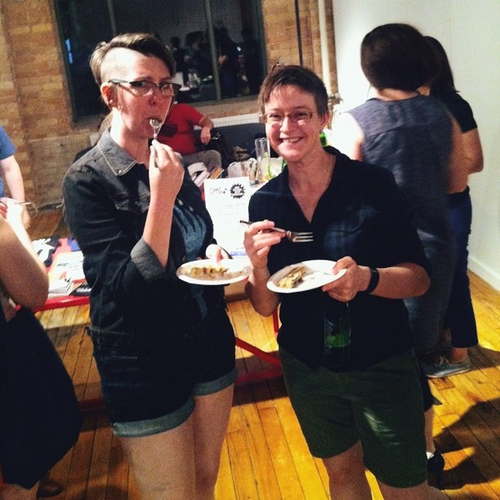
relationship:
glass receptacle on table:
[253, 135, 272, 194] [229, 175, 244, 238]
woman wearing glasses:
[63, 33, 236, 499] [111, 84, 176, 97]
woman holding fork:
[232, 64, 435, 497] [237, 217, 315, 243]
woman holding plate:
[63, 33, 236, 499] [178, 256, 253, 284]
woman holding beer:
[232, 64, 435, 497] [321, 289, 355, 352]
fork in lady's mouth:
[144, 117, 164, 146] [145, 113, 166, 126]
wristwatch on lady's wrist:
[359, 267, 380, 297] [362, 265, 376, 295]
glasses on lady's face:
[106, 73, 176, 98] [126, 55, 174, 134]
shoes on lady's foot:
[429, 358, 478, 379] [419, 33, 486, 373]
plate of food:
[178, 256, 253, 284] [176, 265, 241, 277]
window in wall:
[42, 1, 267, 132] [0, 2, 339, 206]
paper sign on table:
[201, 175, 248, 250] [22, 237, 287, 366]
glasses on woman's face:
[260, 105, 326, 125] [259, 83, 322, 154]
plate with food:
[262, 257, 350, 292] [273, 264, 307, 288]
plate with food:
[178, 256, 253, 284] [185, 263, 239, 280]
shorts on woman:
[87, 323, 239, 439] [63, 33, 236, 499]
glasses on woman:
[111, 84, 176, 97] [63, 33, 236, 499]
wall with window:
[0, 2, 339, 206] [42, 1, 267, 132]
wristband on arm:
[358, 257, 386, 298] [333, 254, 419, 312]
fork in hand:
[237, 219, 314, 242] [241, 213, 289, 270]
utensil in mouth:
[148, 109, 166, 149] [144, 111, 164, 126]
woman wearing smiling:
[232, 64, 435, 497] [273, 133, 306, 142]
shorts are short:
[87, 318, 241, 442] [87, 320, 237, 440]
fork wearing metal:
[231, 219, 311, 251] [237, 216, 316, 244]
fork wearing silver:
[231, 219, 311, 251] [238, 218, 312, 245]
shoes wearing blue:
[429, 358, 478, 379] [431, 355, 454, 375]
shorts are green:
[272, 345, 437, 497] [292, 390, 339, 440]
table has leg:
[16, 219, 295, 386] [224, 323, 286, 369]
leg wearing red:
[224, 323, 286, 369] [238, 337, 252, 347]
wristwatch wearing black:
[359, 265, 381, 297] [367, 278, 376, 288]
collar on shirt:
[94, 126, 135, 178] [62, 127, 246, 367]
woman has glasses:
[63, 33, 236, 499] [102, 68, 180, 101]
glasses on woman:
[260, 105, 326, 125] [232, 64, 435, 497]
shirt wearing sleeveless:
[337, 95, 459, 216] [331, 108, 365, 162]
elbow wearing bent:
[3, 217, 63, 315] [26, 260, 56, 313]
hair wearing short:
[355, 22, 452, 108] [372, 74, 431, 103]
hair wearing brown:
[360, 22, 432, 90] [381, 41, 398, 59]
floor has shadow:
[28, 265, 494, 498] [431, 382, 499, 487]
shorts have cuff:
[82, 318, 247, 442] [106, 390, 198, 443]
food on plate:
[272, 260, 308, 289] [262, 252, 351, 290]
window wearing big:
[42, 1, 267, 132] [41, 0, 277, 120]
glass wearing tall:
[253, 135, 273, 179] [251, 129, 272, 182]